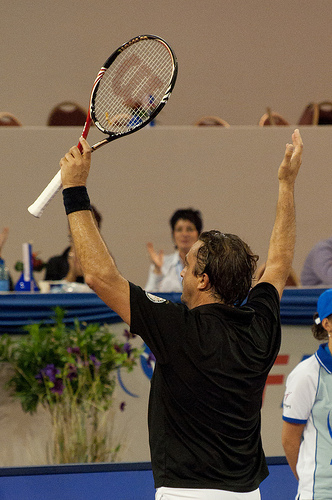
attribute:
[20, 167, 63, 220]
grip — white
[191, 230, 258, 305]
hair — dark, black, wet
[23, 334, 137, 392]
blooms — purple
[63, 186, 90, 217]
band — black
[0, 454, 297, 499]
wall — blue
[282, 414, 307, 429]
stripe — blue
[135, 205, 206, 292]
woman — clapping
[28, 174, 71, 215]
handle — white, .white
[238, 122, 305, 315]
arm — raised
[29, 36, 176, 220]
racket — held, named, colored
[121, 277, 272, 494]
top — black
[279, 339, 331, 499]
shirt — blue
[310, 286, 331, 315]
cap — blue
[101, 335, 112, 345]
leaf — green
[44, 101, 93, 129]
chair — empty, brown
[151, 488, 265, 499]
shorts — white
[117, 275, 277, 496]
shirt — black